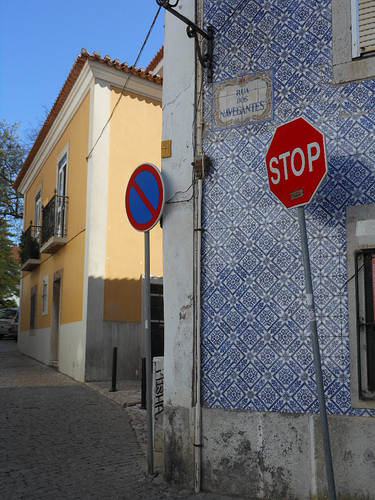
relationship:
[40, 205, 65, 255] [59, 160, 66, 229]
terrace on window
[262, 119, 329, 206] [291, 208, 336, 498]
sign on pole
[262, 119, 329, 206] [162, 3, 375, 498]
sign in front of building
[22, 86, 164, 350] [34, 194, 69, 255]
building has balcony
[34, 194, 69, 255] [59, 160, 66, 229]
balcony near window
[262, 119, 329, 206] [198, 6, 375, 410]
sign by wall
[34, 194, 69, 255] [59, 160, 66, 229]
balcony outside window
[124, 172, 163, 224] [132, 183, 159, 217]
sign has diagonal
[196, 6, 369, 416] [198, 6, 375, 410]
tiles on wall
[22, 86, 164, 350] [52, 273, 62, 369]
building has doorway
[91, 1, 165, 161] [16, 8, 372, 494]
power line connects buildings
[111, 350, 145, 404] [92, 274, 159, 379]
poles near alley